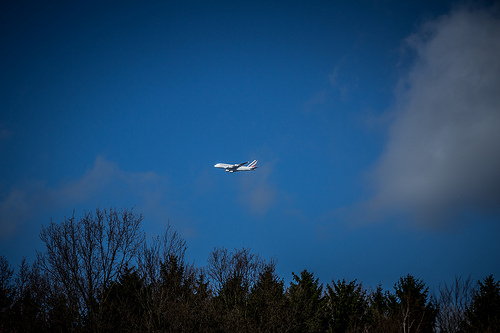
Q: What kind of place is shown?
A: It is a forest.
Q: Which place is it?
A: It is a forest.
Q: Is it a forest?
A: Yes, it is a forest.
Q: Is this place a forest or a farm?
A: It is a forest.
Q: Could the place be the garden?
A: No, it is the forest.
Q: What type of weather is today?
A: It is clear.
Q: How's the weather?
A: It is clear.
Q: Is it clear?
A: Yes, it is clear.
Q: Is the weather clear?
A: Yes, it is clear.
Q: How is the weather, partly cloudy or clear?
A: It is clear.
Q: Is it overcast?
A: No, it is clear.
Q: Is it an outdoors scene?
A: Yes, it is outdoors.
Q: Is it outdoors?
A: Yes, it is outdoors.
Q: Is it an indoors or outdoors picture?
A: It is outdoors.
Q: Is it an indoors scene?
A: No, it is outdoors.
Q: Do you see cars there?
A: No, there are no cars.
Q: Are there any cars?
A: No, there are no cars.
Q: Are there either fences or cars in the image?
A: No, there are no cars or fences.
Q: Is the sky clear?
A: Yes, the sky is clear.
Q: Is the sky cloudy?
A: No, the sky is clear.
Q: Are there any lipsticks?
A: No, there are no lipsticks.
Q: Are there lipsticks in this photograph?
A: No, there are no lipsticks.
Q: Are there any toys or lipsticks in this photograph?
A: No, there are no lipsticks or toys.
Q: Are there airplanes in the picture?
A: Yes, there is an airplane.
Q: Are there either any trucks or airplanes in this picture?
A: Yes, there is an airplane.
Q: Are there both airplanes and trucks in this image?
A: No, there is an airplane but no trucks.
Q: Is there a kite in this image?
A: No, there are no kites.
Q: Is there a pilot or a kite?
A: No, there are no kites or pilots.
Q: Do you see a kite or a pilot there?
A: No, there are no kites or pilots.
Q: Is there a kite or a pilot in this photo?
A: No, there are no kites or pilots.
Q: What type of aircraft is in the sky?
A: The aircraft is an airplane.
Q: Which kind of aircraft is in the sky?
A: The aircraft is an airplane.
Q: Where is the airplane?
A: The airplane is in the sky.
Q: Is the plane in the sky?
A: Yes, the plane is in the sky.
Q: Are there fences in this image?
A: No, there are no fences.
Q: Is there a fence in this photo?
A: No, there are no fences.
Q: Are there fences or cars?
A: No, there are no fences or cars.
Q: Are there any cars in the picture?
A: No, there are no cars.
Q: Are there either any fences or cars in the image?
A: No, there are no cars or fences.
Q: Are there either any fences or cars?
A: No, there are no cars or fences.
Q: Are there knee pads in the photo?
A: No, there are no knee pads.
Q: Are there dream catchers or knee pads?
A: No, there are no knee pads or dream catchers.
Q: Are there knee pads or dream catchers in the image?
A: No, there are no knee pads or dream catchers.